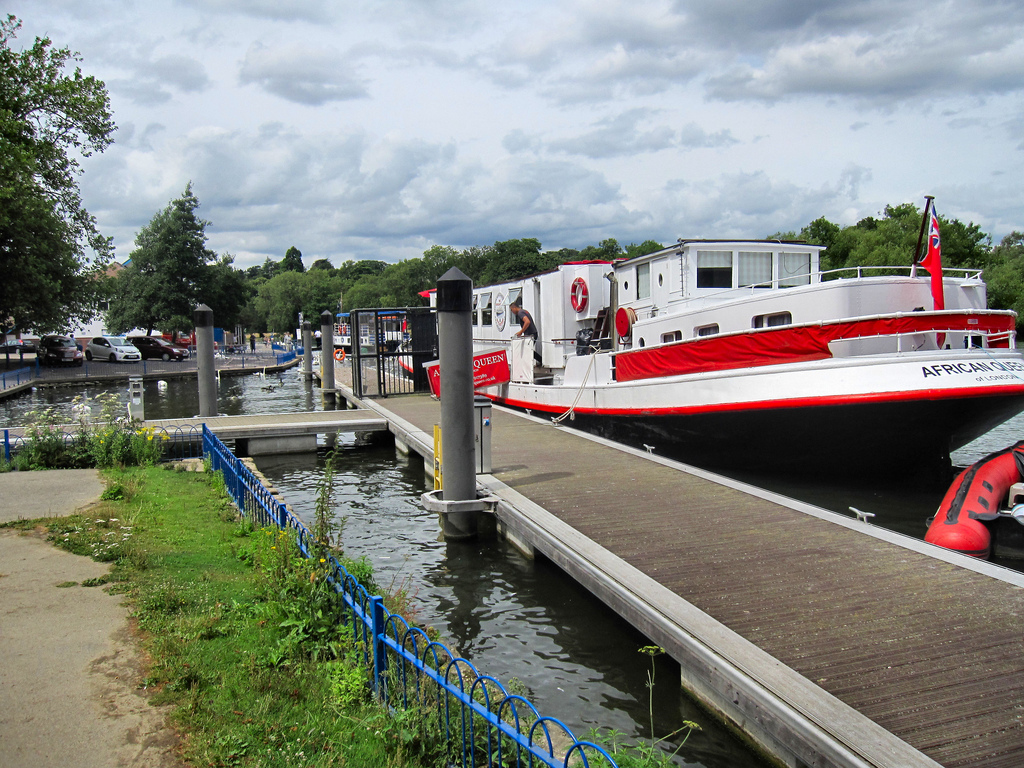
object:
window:
[692, 253, 734, 290]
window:
[748, 313, 795, 337]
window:
[691, 323, 717, 341]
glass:
[636, 336, 647, 349]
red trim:
[588, 375, 1023, 432]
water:
[491, 603, 564, 657]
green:
[173, 505, 209, 550]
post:
[425, 253, 479, 571]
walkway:
[492, 402, 792, 625]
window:
[737, 247, 772, 292]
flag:
[906, 178, 949, 315]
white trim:
[577, 351, 1021, 407]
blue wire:
[299, 508, 486, 715]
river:
[381, 526, 766, 767]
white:
[785, 376, 816, 395]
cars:
[81, 336, 142, 366]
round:
[566, 277, 593, 315]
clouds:
[31, 0, 1023, 213]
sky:
[35, 0, 1023, 239]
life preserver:
[562, 272, 592, 313]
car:
[31, 337, 89, 372]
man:
[498, 301, 548, 371]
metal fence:
[193, 418, 621, 767]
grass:
[95, 437, 293, 763]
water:
[0, 347, 782, 766]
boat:
[382, 208, 1022, 486]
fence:
[241, 505, 540, 748]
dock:
[386, 375, 1024, 737]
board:
[408, 357, 1008, 753]